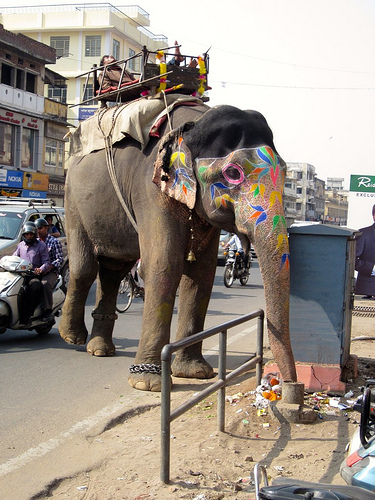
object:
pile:
[253, 370, 282, 414]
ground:
[0, 291, 375, 496]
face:
[218, 125, 288, 236]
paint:
[168, 129, 293, 270]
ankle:
[177, 336, 203, 356]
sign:
[357, 176, 375, 189]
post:
[285, 218, 364, 396]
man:
[12, 220, 42, 327]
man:
[34, 218, 64, 323]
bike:
[0, 255, 70, 339]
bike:
[223, 247, 252, 287]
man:
[98, 41, 198, 90]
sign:
[346, 174, 375, 303]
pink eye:
[222, 163, 244, 185]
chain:
[128, 363, 172, 374]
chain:
[91, 312, 117, 320]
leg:
[136, 191, 186, 361]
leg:
[92, 264, 131, 338]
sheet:
[63, 93, 204, 170]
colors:
[167, 132, 292, 271]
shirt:
[12, 240, 52, 276]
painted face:
[197, 145, 291, 267]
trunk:
[243, 185, 297, 385]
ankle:
[135, 339, 171, 369]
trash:
[225, 333, 375, 446]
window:
[49, 36, 69, 57]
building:
[1, 6, 170, 175]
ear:
[151, 120, 197, 210]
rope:
[96, 101, 138, 235]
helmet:
[22, 221, 37, 244]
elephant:
[58, 94, 298, 393]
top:
[356, 224, 375, 296]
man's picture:
[355, 204, 375, 295]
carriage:
[69, 40, 212, 108]